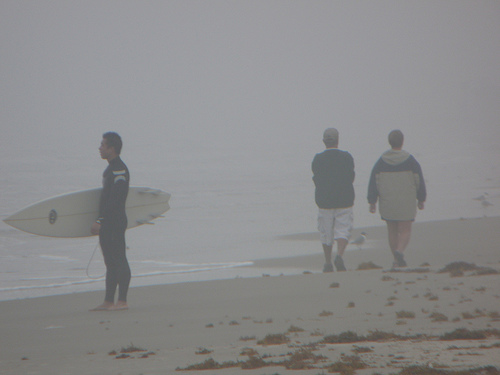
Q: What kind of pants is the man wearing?
A: Shorts.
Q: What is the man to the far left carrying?
A: A surfboard.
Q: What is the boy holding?
A: A board.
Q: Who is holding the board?
A: The boy.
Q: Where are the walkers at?
A: The beach.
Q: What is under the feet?
A: Sand and moss at the beach.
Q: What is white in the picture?
A: The surfboard.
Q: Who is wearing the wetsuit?
A: The boy is.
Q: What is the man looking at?
A: The water.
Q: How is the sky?
A: Very cloudy.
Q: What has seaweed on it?
A: The beach.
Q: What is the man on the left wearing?
A: A wet suit.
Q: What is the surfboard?
A: White.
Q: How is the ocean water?
A: Calm.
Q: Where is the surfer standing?
A: On the sand.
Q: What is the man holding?
A: A white surfboard.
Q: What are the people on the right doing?
A: Walking on the beach.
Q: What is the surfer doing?
A: Looking out at the water.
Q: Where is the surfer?
A: On a beach in fog.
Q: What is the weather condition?
A: Foggy.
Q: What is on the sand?
A: Seaweed.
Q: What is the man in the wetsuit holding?
A: A surfboard.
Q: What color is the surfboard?
A: White.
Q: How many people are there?
A: Three.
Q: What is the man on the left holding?
A: A surfboard.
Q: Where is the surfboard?
A: In the hands of the man on the left.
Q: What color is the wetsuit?
A: Black.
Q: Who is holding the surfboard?
A: The man on the left.